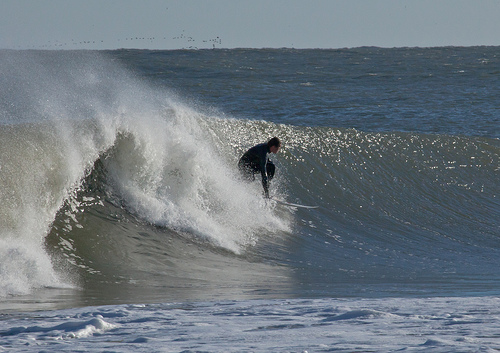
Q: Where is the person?
A: In the water.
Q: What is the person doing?
A: Surfing.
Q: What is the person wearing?
A: A wetsuit.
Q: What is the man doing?
A: Surfing.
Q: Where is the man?
A: Ocean.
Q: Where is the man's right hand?
A: On his surfboard.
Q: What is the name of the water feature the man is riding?
A: Wave.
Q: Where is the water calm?
A: In the distance.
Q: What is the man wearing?
A: Wetsuit.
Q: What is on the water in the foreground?
A: Foam.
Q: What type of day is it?
A: Sunny.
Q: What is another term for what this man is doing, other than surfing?
A: Riding the waves.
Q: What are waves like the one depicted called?
A: Whitecaps.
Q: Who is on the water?
A: A man on a surfboard.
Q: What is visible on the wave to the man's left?
A: Reflection of light.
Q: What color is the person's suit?
A: Black.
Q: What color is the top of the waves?
A: White.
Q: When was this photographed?
A: Daytime.